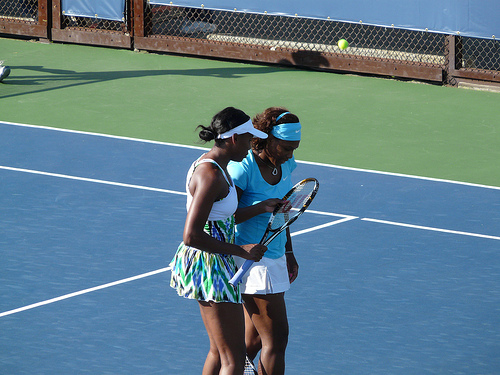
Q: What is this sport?
A: Tennis.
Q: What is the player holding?
A: Racket.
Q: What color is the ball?
A: Bright green.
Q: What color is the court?
A: Blue.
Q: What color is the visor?
A: White.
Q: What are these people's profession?
A: Tennis players.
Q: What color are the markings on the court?
A: White.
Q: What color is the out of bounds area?
A: Green.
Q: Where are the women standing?
A: Tennis court.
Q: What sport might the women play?
A: Tennis.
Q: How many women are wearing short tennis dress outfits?
A: Two.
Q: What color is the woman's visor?
A: White.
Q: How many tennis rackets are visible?
A: One.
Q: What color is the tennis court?
A: Blue.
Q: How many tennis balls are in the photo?
A: One.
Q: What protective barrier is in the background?
A: Fence.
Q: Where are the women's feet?
A: Not in picture.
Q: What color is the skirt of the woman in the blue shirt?
A: White.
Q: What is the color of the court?
A: Blue.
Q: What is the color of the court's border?
A: Green.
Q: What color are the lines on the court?
A: White.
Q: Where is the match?
A: On a tennis court.